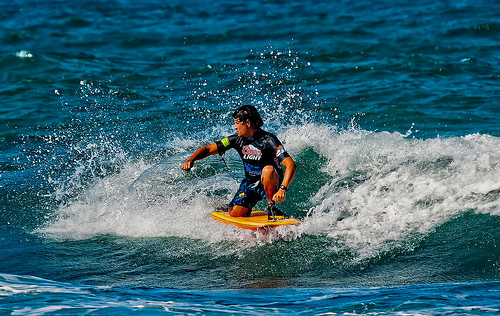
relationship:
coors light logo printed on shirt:
[241, 142, 265, 164] [212, 130, 288, 183]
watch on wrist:
[277, 184, 288, 191] [276, 180, 289, 193]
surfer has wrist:
[175, 103, 300, 219] [276, 180, 289, 193]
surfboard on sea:
[210, 203, 298, 235] [3, 1, 497, 310]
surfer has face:
[175, 103, 300, 219] [233, 117, 245, 138]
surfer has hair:
[175, 103, 300, 219] [231, 103, 262, 131]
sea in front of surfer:
[3, 1, 497, 310] [175, 103, 300, 219]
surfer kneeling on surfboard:
[175, 103, 300, 219] [210, 203, 298, 235]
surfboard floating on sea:
[210, 203, 298, 235] [3, 1, 497, 310]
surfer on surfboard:
[175, 103, 300, 219] [210, 203, 298, 235]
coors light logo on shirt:
[241, 142, 265, 164] [212, 130, 288, 183]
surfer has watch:
[175, 103, 300, 219] [277, 184, 288, 191]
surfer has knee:
[175, 103, 300, 219] [229, 204, 248, 218]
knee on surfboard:
[229, 204, 248, 218] [210, 203, 298, 235]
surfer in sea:
[175, 103, 300, 219] [3, 1, 497, 310]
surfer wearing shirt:
[175, 103, 300, 219] [212, 130, 288, 183]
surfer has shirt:
[175, 103, 300, 219] [212, 130, 288, 183]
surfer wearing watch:
[175, 103, 300, 219] [277, 184, 288, 191]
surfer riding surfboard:
[175, 103, 300, 219] [210, 203, 298, 235]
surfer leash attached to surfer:
[221, 156, 274, 206] [175, 103, 300, 219]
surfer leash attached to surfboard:
[221, 156, 274, 206] [210, 203, 298, 235]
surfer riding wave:
[175, 103, 300, 219] [10, 123, 499, 271]